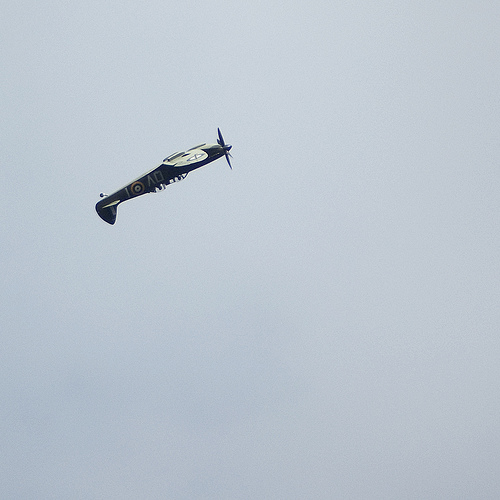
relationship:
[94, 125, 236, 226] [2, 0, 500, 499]
plane in sky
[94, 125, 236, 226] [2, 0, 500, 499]
jet in sky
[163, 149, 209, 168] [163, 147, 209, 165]
wing has bottom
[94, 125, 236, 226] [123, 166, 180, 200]
jet has side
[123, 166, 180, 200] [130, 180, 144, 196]
side has target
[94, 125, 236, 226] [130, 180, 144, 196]
jet has target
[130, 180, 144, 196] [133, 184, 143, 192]
target has circle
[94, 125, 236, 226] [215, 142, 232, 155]
jet has front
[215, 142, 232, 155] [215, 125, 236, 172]
front has propeller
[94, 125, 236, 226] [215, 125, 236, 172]
jet has propeller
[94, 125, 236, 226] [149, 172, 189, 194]
jet has cockpit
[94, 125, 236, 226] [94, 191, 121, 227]
jet has back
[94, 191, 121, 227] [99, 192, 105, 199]
back has wheel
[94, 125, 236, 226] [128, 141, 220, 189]
jet has underbelly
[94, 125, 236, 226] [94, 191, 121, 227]
jet has rear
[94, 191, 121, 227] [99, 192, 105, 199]
rear has wheel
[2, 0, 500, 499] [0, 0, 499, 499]
sky has clouds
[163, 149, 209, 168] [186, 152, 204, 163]
wing has logo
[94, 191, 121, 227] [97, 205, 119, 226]
back has tail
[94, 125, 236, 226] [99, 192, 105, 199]
jet has wheel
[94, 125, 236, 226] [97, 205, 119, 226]
jet has tail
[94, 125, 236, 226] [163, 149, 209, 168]
jet has wing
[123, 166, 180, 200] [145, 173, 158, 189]
side has letter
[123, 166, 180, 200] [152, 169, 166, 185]
side has letter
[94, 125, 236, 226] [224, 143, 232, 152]
jet has engine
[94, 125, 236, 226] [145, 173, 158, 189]
jet has letter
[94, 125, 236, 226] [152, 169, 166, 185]
jet has letter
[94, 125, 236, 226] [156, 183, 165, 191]
jet has person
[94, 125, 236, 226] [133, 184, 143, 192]
jet has circle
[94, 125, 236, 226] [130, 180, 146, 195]
jet has circle